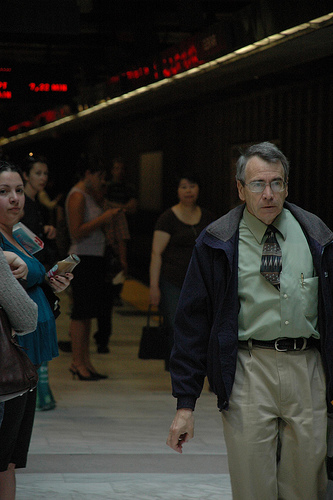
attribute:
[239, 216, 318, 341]
shirt — green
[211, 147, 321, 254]
man — walking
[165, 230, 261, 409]
jacket — blue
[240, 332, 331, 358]
belt — black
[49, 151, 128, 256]
woman — texting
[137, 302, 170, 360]
purse — black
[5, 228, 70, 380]
blouse — green